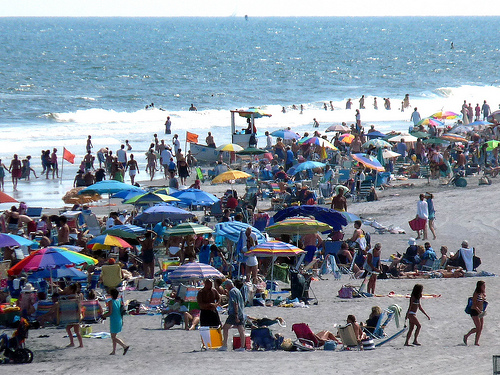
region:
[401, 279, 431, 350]
Girl walking on the beach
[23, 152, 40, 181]
Girl kicking the water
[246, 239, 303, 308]
A beach umbrella in the sand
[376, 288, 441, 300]
Towel on the beach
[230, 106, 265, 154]
A lifeguard tower on beach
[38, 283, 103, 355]
Person holding a beach chair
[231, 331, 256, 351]
A red cooler on sand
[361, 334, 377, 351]
A blue and white bag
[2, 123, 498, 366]
People on the beach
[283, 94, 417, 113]
People in the water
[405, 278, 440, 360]
This is a person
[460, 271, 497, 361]
This is a person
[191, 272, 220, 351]
This is a person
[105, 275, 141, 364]
This is a person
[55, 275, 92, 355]
This is a person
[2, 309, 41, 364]
This is a person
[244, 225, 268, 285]
This is a person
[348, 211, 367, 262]
This is a person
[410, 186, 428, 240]
This is a person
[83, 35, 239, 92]
The water is choppy.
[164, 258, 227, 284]
The umbrella is striped.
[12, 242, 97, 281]
The umbrella is multi colored.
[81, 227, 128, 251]
The umbrella is multi colored.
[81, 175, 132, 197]
The umbrella is blue.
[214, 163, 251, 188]
The umbrella is yellow.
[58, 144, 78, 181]
The flag is red.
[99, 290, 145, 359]
The woman is wearing a blue dress.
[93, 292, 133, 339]
The woman's dress is sleeveless.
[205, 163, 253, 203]
large umbrella on the beach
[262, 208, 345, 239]
large umbrella on the beach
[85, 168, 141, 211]
large umbrella on the beach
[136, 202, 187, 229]
large umbrella on the beach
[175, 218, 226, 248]
large umbrella on the beach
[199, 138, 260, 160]
large umbrella on the beach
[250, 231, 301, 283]
large umbrella on the beach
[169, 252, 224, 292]
large umbrella on the beach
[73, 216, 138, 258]
large umbrella on the beach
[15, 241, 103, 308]
large umbrella on the beach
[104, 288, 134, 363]
woman in a blue dress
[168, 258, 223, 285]
purple and pink umbrella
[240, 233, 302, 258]
blue and orange umbrella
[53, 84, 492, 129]
white top of wave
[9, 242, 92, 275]
rainbow multi colored umbrella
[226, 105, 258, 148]
life guard stand in the distance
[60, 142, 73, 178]
orange flag near the shore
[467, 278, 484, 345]
person holding a beach chair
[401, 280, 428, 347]
woman walking away from beach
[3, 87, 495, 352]
large group of people on the beach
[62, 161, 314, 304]
lots of people on the beach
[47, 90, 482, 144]
waves off in the ocean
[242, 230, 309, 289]
rainbow umbrella in the sand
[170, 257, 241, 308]
purple and pink umbrella in the sand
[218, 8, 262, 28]
ship out in the distance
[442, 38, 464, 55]
man in the ocean in the water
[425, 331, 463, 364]
sand on the beach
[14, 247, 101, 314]
a largeu open umbrella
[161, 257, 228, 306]
a large open umbrella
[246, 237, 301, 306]
a large open umbrella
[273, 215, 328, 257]
a large open umbrella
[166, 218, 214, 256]
a large open umbrella